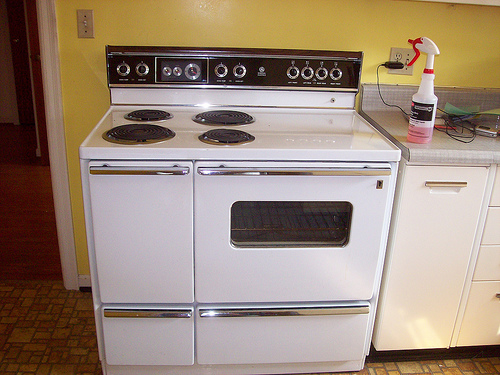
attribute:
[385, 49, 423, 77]
outlet — beige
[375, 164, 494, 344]
cabinet — white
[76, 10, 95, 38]
switch — beige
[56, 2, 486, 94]
wall — yellow, painted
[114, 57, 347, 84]
knobs — black, gray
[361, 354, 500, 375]
tiles — brown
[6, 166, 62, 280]
floor — brown, wooden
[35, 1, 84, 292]
doorway — white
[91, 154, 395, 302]
oven — black, large, white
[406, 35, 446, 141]
bottle — cleaning agent, red, white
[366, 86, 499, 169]
counter — gray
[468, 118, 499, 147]
cell phone — gray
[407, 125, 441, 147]
cleaning agent — pink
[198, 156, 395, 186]
handle — metal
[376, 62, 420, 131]
cord — black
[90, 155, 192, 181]
handle — silver